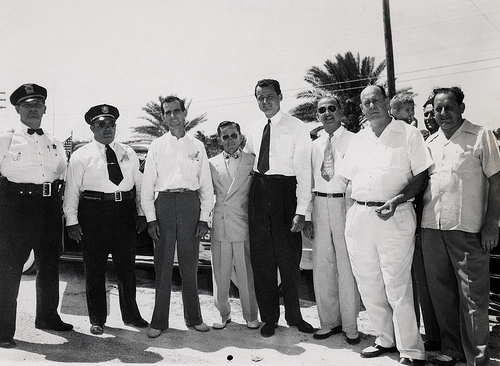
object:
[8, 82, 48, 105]
cap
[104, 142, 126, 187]
tie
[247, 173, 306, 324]
slacks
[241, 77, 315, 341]
man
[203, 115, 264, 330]
short man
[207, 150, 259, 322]
suit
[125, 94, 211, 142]
trees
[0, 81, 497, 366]
group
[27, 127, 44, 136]
bowtie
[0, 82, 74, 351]
man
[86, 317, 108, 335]
shoes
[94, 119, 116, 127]
sunglasses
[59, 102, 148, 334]
man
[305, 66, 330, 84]
leaves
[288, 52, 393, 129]
tree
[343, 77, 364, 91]
section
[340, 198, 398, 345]
right leg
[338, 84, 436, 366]
man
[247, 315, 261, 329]
left foot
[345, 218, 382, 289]
section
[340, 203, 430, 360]
white trouser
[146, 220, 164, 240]
right hand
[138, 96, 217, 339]
man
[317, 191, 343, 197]
section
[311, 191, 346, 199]
belt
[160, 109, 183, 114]
sunglasses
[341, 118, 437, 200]
shirt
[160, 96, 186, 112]
dark hair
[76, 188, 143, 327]
pants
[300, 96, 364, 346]
man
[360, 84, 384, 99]
bald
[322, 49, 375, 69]
top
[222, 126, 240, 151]
face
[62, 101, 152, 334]
police officer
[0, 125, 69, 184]
shirt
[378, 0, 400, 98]
pole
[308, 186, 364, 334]
pants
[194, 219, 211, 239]
left hand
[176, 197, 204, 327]
left leg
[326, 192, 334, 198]
belt buckle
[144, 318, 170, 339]
right foot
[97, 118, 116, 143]
face of man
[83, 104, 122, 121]
cap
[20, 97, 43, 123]
face of man